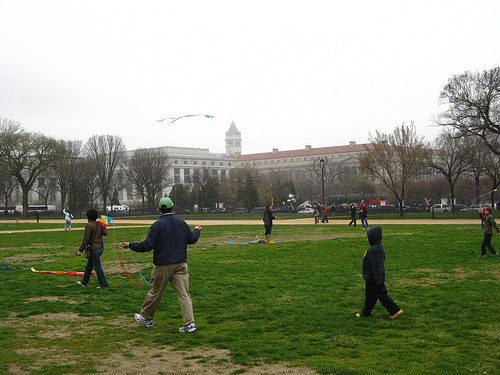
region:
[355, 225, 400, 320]
child in dark pants in jacket walking on field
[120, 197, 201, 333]
adult in blue jacket and khaki pants helping with kite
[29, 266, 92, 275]
kite on ground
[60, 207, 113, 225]
trying to get a kite in the air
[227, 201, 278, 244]
kite flyer with kite on ground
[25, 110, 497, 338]
people flying kites on field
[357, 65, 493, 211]
deciduous trees with no leaves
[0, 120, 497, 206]
large institutional style buildings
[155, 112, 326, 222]
successful kite flyers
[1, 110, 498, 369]
flying kites on a large city field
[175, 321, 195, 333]
the shoe of a man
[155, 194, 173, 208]
a green baseball cap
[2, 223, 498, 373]
a large section of green grass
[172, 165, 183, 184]
a window of a building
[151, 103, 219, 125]
a long colorful kite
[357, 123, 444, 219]
a tall green tree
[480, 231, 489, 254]
the leg of a boy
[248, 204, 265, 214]
part of a vehicle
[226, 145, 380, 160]
the roof of a building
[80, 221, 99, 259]
a woman's purse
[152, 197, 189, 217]
a green hat on head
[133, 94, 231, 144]
a kite in the sky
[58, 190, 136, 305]
a kite in hand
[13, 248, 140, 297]
long tail of kite on ground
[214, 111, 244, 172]
a steeple on a building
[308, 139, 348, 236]
a black lamp post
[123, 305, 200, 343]
white and blue shoes on feet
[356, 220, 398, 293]
a black shirt with hood up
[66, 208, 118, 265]
a black purse carried over the shoulder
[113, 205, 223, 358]
a blue jacket and tan pants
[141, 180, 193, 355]
PERSON WALKING ON GRASS FIELD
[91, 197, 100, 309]
PERSON WALKING ON GRASS FIELD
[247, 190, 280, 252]
PERSON WALKING ON GRASS FIELD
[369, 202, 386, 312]
PERSON WALKING ON GRASS FIELD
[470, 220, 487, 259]
PERSON WALKING ON GRASS FIELD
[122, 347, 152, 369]
DIRT PATCHES IN GRASS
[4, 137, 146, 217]
TREES GROWING IN FRONT OF BUILDINGS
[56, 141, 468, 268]
LARGE BUILDING IN BACKGROUND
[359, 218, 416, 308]
BLUE HOODIE ON SMALL BOY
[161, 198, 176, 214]
GREEN CAP ON PERSON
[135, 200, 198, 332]
man with a green had and blue jacket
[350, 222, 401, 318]
little boy with blue hoodie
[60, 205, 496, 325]
people flying kites on the National Mall in DC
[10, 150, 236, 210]
white building on the left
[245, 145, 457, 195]
building with red tile roof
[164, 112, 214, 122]
kite flying in the air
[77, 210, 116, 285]
woman with brown jacket near rainbow kite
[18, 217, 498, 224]
long dirt path crossing the grass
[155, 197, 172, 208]
green baseball cap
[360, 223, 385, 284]
navy blue hoodie